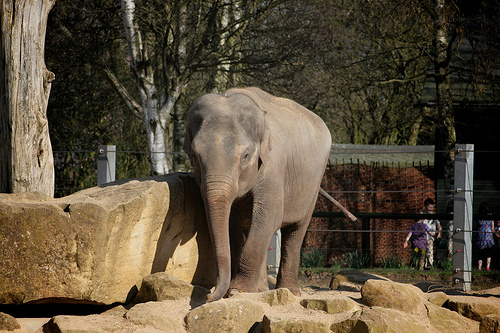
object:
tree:
[82, 2, 225, 177]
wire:
[386, 150, 455, 156]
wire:
[358, 176, 443, 196]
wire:
[357, 228, 425, 234]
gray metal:
[447, 141, 476, 294]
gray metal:
[96, 143, 118, 189]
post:
[452, 142, 473, 292]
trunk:
[188, 167, 236, 303]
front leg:
[226, 186, 283, 300]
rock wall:
[0, 178, 247, 300]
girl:
[473, 201, 496, 272]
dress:
[476, 218, 495, 249]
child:
[403, 216, 435, 268]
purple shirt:
[409, 221, 431, 247]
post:
[96, 140, 119, 186]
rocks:
[45, 316, 139, 333]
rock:
[0, 170, 216, 304]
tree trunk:
[4, 0, 53, 210]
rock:
[363, 278, 429, 315]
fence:
[306, 156, 500, 299]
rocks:
[185, 297, 269, 333]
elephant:
[175, 85, 335, 302]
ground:
[0, 262, 497, 333]